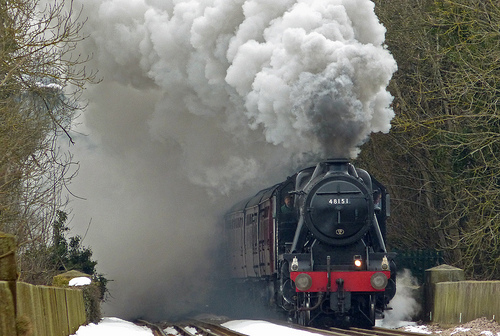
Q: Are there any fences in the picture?
A: Yes, there is a fence.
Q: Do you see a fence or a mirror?
A: Yes, there is a fence.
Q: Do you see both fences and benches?
A: No, there is a fence but no benches.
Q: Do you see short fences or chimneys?
A: Yes, there is a short fence.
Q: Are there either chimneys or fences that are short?
A: Yes, the fence is short.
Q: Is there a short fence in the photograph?
A: Yes, there is a short fence.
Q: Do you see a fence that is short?
A: Yes, there is a fence that is short.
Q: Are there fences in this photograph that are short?
A: Yes, there is a fence that is short.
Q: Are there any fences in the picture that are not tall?
A: Yes, there is a short fence.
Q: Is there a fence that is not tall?
A: Yes, there is a short fence.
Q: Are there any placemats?
A: No, there are no placemats.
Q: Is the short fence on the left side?
A: Yes, the fence is on the left of the image.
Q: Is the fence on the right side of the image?
A: No, the fence is on the left of the image.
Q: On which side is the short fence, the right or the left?
A: The fence is on the left of the image.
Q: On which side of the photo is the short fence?
A: The fence is on the left of the image.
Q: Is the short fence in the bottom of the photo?
A: Yes, the fence is in the bottom of the image.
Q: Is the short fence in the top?
A: No, the fence is in the bottom of the image.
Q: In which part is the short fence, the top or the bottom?
A: The fence is in the bottom of the image.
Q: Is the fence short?
A: Yes, the fence is short.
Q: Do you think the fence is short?
A: Yes, the fence is short.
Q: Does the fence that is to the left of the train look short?
A: Yes, the fence is short.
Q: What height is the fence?
A: The fence is short.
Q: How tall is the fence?
A: The fence is short.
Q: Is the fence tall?
A: No, the fence is short.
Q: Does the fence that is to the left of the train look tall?
A: No, the fence is short.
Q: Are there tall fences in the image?
A: No, there is a fence but it is short.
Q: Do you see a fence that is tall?
A: No, there is a fence but it is short.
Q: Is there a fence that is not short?
A: No, there is a fence but it is short.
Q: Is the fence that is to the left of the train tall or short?
A: The fence is short.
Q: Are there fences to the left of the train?
A: Yes, there is a fence to the left of the train.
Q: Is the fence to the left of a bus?
A: No, the fence is to the left of the train.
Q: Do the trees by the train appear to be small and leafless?
A: Yes, the trees are small and leafless.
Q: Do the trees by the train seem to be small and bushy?
A: No, the trees are small but leafless.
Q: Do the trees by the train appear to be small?
A: Yes, the trees are small.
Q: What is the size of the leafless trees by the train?
A: The trees are small.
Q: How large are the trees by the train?
A: The trees are small.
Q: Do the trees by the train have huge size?
A: No, the trees are small.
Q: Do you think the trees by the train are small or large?
A: The trees are small.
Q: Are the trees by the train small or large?
A: The trees are small.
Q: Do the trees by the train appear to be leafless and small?
A: Yes, the trees are leafless and small.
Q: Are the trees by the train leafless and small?
A: Yes, the trees are leafless and small.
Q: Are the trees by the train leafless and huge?
A: No, the trees are leafless but small.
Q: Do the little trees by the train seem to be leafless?
A: Yes, the trees are leafless.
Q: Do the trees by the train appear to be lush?
A: No, the trees are leafless.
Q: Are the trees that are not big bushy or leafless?
A: The trees are leafless.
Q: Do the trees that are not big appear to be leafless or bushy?
A: The trees are leafless.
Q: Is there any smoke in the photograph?
A: Yes, there is smoke.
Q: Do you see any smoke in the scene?
A: Yes, there is smoke.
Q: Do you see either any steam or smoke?
A: Yes, there is smoke.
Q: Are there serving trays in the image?
A: No, there are no serving trays.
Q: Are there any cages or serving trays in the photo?
A: No, there are no serving trays or cages.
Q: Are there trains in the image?
A: Yes, there is a train.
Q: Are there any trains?
A: Yes, there is a train.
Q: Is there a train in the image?
A: Yes, there is a train.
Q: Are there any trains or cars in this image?
A: Yes, there is a train.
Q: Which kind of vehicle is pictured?
A: The vehicle is a train.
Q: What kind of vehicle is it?
A: The vehicle is a train.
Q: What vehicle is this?
A: This is a train.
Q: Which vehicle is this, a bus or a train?
A: This is a train.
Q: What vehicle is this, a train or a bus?
A: This is a train.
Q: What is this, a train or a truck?
A: This is a train.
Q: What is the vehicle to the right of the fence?
A: The vehicle is a train.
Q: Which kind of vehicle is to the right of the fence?
A: The vehicle is a train.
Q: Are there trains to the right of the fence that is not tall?
A: Yes, there is a train to the right of the fence.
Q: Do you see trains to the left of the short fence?
A: No, the train is to the right of the fence.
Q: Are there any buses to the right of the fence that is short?
A: No, there is a train to the right of the fence.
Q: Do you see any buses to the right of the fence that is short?
A: No, there is a train to the right of the fence.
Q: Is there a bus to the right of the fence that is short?
A: No, there is a train to the right of the fence.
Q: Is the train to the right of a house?
A: No, the train is to the right of the fence.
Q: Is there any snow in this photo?
A: Yes, there is snow.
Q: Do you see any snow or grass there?
A: Yes, there is snow.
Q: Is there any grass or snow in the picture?
A: Yes, there is snow.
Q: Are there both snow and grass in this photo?
A: No, there is snow but no grass.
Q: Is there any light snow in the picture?
A: Yes, there is light snow.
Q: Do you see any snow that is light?
A: Yes, there is light snow.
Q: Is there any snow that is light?
A: Yes, there is snow that is light.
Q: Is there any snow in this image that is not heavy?
A: Yes, there is light snow.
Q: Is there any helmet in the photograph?
A: No, there are no helmets.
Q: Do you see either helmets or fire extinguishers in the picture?
A: No, there are no helmets or fire extinguishers.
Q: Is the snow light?
A: Yes, the snow is light.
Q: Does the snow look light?
A: Yes, the snow is light.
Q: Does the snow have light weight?
A: Yes, the snow is light.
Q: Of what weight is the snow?
A: The snow is light.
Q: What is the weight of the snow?
A: The snow is light.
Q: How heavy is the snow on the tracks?
A: The snow is light.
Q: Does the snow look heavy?
A: No, the snow is light.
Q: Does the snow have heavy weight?
A: No, the snow is light.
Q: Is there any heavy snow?
A: No, there is snow but it is light.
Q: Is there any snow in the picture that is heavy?
A: No, there is snow but it is light.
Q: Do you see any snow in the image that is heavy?
A: No, there is snow but it is light.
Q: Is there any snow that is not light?
A: No, there is snow but it is light.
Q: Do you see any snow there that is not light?
A: No, there is snow but it is light.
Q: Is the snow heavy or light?
A: The snow is light.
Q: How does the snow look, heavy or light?
A: The snow is light.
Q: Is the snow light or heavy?
A: The snow is light.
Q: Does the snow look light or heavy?
A: The snow is light.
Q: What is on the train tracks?
A: The snow is on the train tracks.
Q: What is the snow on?
A: The snow is on the railroad tracks.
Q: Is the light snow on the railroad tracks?
A: Yes, the snow is on the railroad tracks.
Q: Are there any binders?
A: No, there are no binders.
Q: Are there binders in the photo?
A: No, there are no binders.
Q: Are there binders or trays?
A: No, there are no binders or trays.